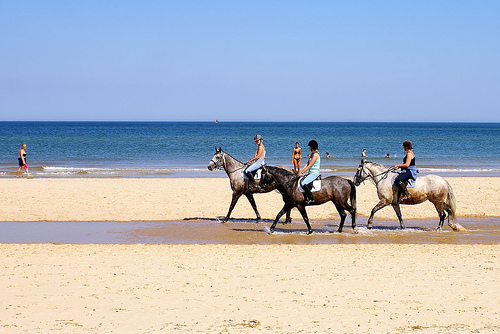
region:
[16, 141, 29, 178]
person walking along the ocean's edge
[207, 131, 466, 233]
group of people riding horses on the beach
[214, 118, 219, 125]
sailboat off in the distance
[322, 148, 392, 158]
people swimming in the ocean water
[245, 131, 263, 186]
woman wearing a riding helmet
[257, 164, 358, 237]
horse walking in water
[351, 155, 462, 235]
white horse walking in water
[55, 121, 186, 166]
calm blue ocean waters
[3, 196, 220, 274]
water in between areas of sand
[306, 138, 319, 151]
black riding helmet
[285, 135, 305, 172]
woman walking up from beach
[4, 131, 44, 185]
woman walking along the beach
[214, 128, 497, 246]
three horses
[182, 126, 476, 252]
horses walking on the beach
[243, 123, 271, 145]
rider wearing a helmet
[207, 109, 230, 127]
boat on the water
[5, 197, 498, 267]
water on the sand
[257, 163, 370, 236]
dark brown horse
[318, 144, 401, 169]
people in the water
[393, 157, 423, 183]
woman has jacket tied around the waist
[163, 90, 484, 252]
these people are horseback riding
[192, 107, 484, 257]
there are three people riding horses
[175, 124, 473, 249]
they are riding horses on a beach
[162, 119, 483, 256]
the horses are walking in water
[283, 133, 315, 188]
she is wearing a bikini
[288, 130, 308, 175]
her swimsuit is black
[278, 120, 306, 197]
this woman is wearing a black bikini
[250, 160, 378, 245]
this horse is darker than the others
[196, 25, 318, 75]
sky with no clouds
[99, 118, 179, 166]
water in the photo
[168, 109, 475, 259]
many horses in the photo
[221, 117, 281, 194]
person on the horse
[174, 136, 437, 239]
three horses in photo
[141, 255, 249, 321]
sand on the ground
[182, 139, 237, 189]
head of the horse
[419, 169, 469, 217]
back of the horse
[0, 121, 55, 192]
person on the beach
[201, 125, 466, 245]
three women on a horse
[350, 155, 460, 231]
the horse is white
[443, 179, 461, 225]
long tail of horse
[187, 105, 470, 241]
horses on front a beach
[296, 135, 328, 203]
woman wears a blue top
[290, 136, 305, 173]
woman wears a bikini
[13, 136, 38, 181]
woman holds a red Frisbee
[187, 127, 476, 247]
horses walking on wet sand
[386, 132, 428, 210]
woman wears a black top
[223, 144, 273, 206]
a horse on the beach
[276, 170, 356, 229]
a horse on the beach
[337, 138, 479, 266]
a horse on the beach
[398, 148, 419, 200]
a person riding a horse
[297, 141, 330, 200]
a person riding a horse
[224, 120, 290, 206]
a person riding a horse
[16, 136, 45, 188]
a person in the water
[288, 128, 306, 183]
a person in the water